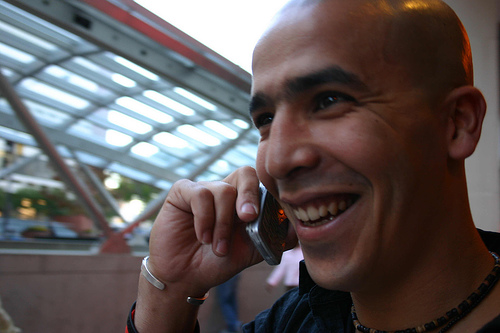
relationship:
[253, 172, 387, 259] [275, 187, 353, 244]
mouth showing teeth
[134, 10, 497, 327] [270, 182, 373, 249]
man with a smile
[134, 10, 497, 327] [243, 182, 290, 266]
man talking on cellphone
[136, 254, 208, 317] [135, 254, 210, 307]
wrist with silver bracelet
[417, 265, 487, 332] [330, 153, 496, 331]
necklace around neck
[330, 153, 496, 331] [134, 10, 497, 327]
neck of man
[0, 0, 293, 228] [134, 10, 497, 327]
sky behind man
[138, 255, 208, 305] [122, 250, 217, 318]
watch on wrist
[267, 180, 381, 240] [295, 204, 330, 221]
smile showing teeth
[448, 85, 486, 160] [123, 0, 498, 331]
ear on bald man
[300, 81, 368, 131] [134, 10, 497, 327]
eye of man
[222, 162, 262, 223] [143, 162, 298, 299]
fingers on hand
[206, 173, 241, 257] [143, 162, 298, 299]
fingers on hand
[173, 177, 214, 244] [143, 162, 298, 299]
fingers on hand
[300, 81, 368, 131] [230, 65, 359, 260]
eye of man's face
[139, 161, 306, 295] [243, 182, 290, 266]
hand holding cellphone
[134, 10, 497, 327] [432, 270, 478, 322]
man wearing necklace